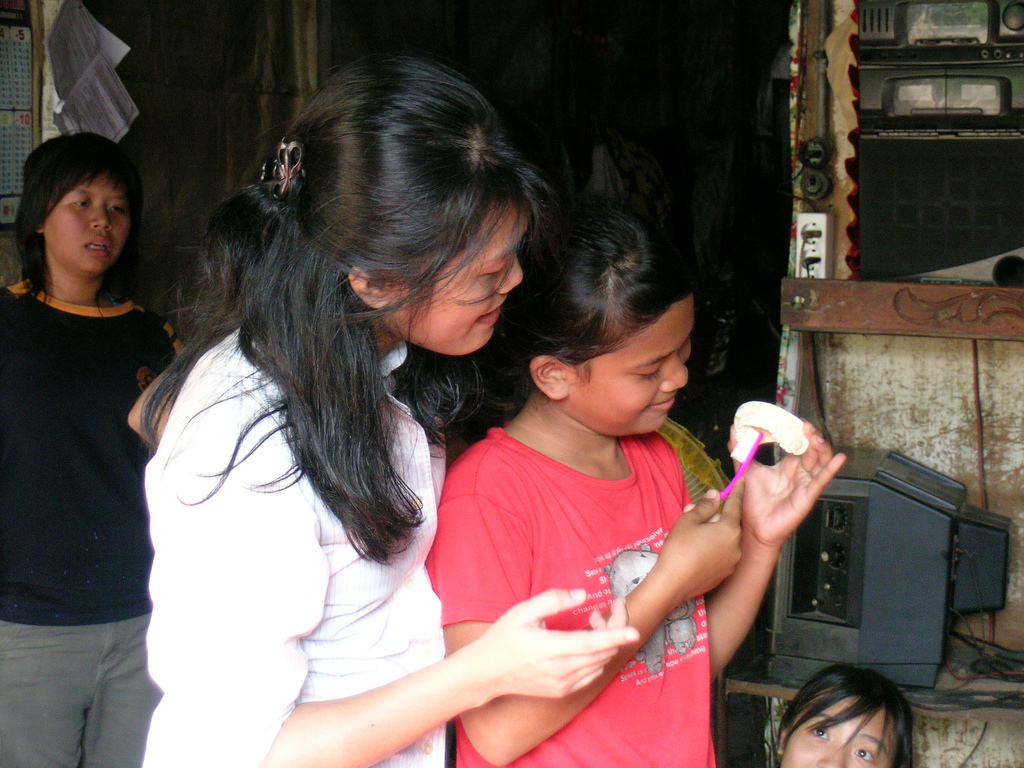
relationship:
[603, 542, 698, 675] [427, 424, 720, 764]
bear on tee shirt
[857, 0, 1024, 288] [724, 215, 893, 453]
stereo system machine with double sided cassette player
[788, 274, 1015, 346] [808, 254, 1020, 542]
shelf hanging on wall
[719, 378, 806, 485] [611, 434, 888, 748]
model denture teaching aide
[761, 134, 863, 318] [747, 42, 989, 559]
power strip hanging on wall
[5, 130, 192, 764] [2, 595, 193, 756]
woman wearing pants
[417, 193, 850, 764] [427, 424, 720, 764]
child wearing tee shirt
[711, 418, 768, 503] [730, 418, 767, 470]
toothbrush with bristles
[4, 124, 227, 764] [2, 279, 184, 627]
woman wearing shirt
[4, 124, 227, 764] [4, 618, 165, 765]
woman wearing pants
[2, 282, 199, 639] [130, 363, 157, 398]
shirt with accent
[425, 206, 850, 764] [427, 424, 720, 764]
child wearing tee shirt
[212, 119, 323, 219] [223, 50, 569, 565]
hair clip in hair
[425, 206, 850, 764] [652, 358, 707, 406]
child has nose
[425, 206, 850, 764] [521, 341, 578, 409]
child has ear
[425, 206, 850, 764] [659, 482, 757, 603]
child has hand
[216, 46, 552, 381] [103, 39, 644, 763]
head of woman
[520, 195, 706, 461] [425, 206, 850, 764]
head of child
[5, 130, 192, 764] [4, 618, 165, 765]
woman wearing pants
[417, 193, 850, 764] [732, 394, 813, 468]
child holding teeth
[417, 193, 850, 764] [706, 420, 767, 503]
child holding toothbrush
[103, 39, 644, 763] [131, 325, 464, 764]
woman wearing shirt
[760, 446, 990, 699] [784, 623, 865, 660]
television with dust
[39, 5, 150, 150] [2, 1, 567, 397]
papers on wall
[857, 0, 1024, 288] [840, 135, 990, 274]
stereo system with speakers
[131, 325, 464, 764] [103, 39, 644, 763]
shirt on woman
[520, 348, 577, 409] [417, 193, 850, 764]
ear of child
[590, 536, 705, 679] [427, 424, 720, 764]
bear on tee shirt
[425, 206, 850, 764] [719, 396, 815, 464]
child holding teeth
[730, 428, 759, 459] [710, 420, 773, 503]
bristles on brush